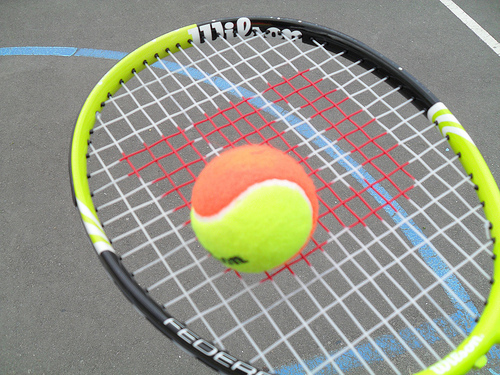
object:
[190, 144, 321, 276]
ball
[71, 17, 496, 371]
racquet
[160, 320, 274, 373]
endorsement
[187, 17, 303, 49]
wilson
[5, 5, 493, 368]
court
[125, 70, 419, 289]
"w"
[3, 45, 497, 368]
lines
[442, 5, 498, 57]
line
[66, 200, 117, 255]
design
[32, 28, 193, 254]
edge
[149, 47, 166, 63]
hole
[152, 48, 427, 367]
string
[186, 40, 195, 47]
hole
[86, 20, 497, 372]
string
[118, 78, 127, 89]
hole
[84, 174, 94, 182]
hole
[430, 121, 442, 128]
hole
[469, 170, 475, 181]
hole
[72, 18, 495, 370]
rim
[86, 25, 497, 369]
strings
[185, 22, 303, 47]
letters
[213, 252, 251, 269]
writing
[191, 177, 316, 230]
seam